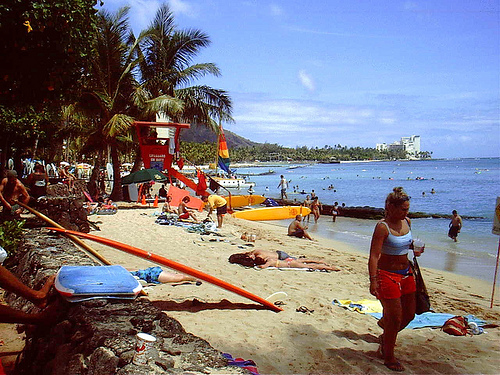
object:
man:
[288, 214, 315, 241]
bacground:
[219, 132, 437, 166]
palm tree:
[119, 0, 236, 177]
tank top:
[378, 219, 413, 256]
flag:
[215, 125, 237, 178]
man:
[0, 170, 31, 219]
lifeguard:
[158, 185, 167, 198]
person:
[201, 194, 228, 228]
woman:
[254, 257, 342, 271]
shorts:
[374, 263, 418, 300]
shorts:
[217, 203, 228, 215]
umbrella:
[121, 168, 168, 208]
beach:
[0, 185, 500, 374]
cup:
[413, 240, 425, 252]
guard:
[147, 131, 162, 144]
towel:
[332, 298, 492, 336]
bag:
[440, 315, 474, 337]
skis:
[45, 227, 285, 313]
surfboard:
[45, 227, 284, 313]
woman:
[368, 186, 435, 371]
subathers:
[140, 175, 394, 295]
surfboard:
[222, 194, 266, 208]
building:
[375, 134, 421, 159]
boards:
[231, 206, 313, 223]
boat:
[188, 177, 256, 188]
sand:
[93, 211, 500, 375]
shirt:
[207, 194, 227, 209]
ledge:
[6, 226, 255, 375]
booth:
[122, 121, 191, 203]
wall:
[0, 228, 258, 375]